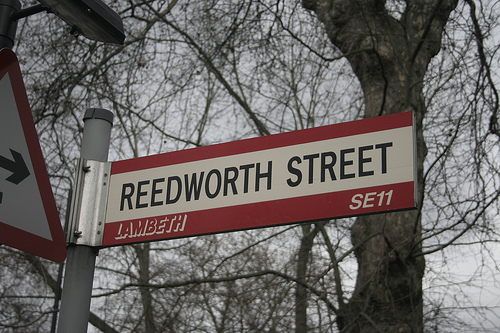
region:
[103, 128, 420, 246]
street sign in white red and black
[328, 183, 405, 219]
SE11 in white on the red stripe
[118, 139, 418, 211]
street name is Reedworth Street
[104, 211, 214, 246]
Lambeth printed in white outline on red sign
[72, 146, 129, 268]
silver bracket holding street sign to post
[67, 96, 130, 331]
post that holds up the street sign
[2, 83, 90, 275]
triangular sign with a red border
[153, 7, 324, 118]
tangled branches of the leafless tree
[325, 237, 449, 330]
thick trunk on the tall tree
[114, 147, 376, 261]
sign has white stripe through the middle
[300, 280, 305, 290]
part of a branch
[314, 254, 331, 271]
edge of a branch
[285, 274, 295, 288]
edge of a twig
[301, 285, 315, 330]
part of a branch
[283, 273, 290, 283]
edge of a twig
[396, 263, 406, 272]
side of a tree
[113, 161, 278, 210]
The sign says Reedworth.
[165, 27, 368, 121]
none of the branches have leaves.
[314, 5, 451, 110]
The tree is extremely tall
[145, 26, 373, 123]
The sky is filled with clouds.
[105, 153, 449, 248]
This is Reedworth Street.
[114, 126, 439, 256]
The sign is colored red and white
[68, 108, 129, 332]
A Grey pole holds up the signs.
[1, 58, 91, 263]
The shape of the sign is triangle.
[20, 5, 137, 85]
An street light to light up the sign.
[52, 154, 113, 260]
A metal plating that holds the sign tight.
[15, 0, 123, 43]
sqaure light on pole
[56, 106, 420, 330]
sign on gray pole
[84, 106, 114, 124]
cracked cap on pole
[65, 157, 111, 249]
metal brace on pole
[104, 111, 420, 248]
sign with black words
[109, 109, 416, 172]
red edge of sign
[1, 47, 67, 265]
sign with black arrow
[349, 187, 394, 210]
white characters on sign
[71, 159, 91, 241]
two screws in metal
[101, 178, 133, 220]
the letter R on sign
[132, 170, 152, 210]
the letter E on sign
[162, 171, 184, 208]
the letter D on sign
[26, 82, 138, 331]
a grey steel pole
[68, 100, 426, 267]
a red and white sign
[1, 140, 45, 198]
a black arrow on a sign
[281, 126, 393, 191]
the word street on sign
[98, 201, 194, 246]
the word lambeth on sign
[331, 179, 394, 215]
the word SE11 on the sign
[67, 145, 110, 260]
a metal bracket on the sign